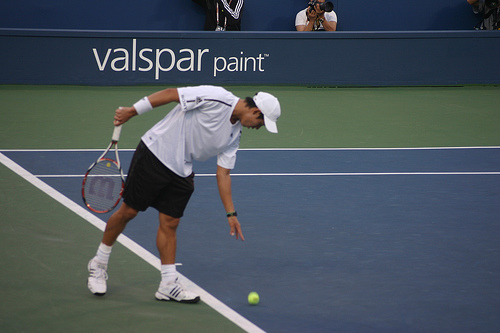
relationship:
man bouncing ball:
[295, 0, 337, 31] [245, 292, 261, 304]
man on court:
[295, 0, 337, 31] [4, 84, 497, 324]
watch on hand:
[227, 214, 238, 219] [226, 212, 246, 241]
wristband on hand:
[126, 97, 157, 117] [113, 105, 136, 126]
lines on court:
[6, 146, 498, 332] [4, 84, 497, 324]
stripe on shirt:
[187, 95, 231, 111] [137, 84, 238, 178]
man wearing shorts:
[295, 0, 337, 31] [121, 137, 195, 216]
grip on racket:
[109, 106, 125, 146] [80, 105, 124, 215]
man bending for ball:
[295, 0, 337, 31] [245, 292, 261, 304]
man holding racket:
[295, 0, 337, 31] [80, 105, 124, 215]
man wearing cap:
[295, 0, 337, 31] [251, 89, 282, 135]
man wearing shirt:
[295, 0, 337, 31] [140, 87, 242, 179]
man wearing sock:
[295, 0, 337, 31] [89, 242, 114, 265]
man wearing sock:
[295, 0, 337, 31] [161, 258, 178, 284]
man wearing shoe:
[295, 0, 337, 31] [83, 256, 108, 296]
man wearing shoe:
[295, 0, 337, 31] [156, 282, 200, 305]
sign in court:
[89, 35, 277, 80] [4, 84, 497, 324]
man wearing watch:
[295, 0, 337, 31] [227, 214, 238, 219]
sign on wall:
[89, 35, 277, 80] [8, 32, 498, 86]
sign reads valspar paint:
[89, 35, 277, 80] [93, 36, 268, 75]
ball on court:
[245, 292, 261, 304] [4, 84, 497, 324]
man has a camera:
[297, 5, 344, 31] [310, 1, 336, 14]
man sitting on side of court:
[297, 5, 344, 31] [4, 4, 496, 28]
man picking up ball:
[295, 0, 337, 31] [245, 292, 261, 304]